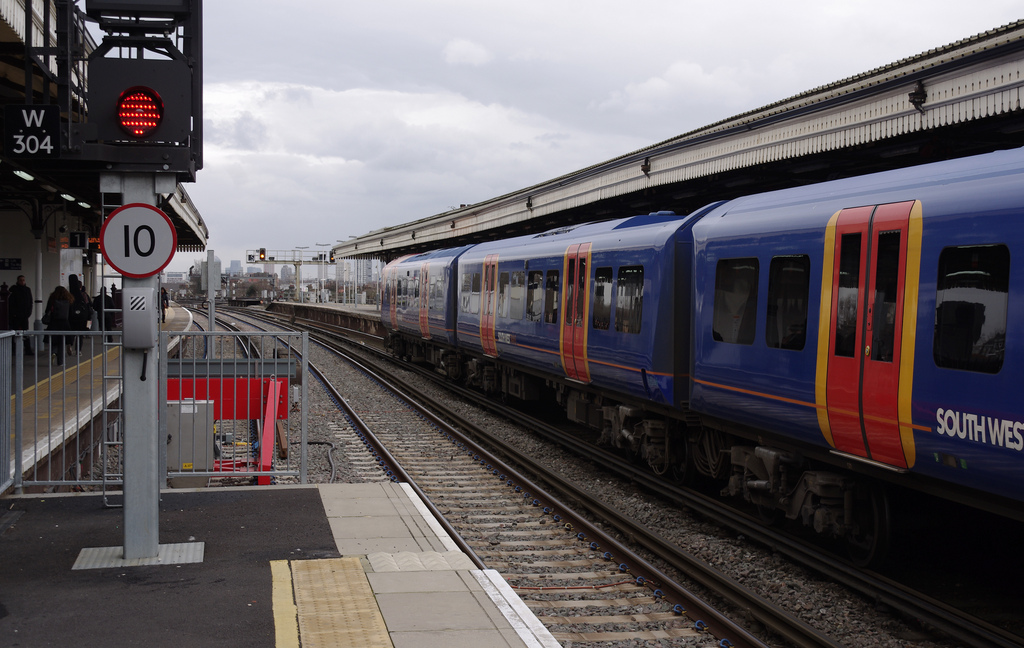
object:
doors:
[807, 192, 928, 476]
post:
[39, 100, 252, 593]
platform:
[0, 176, 427, 644]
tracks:
[222, 299, 1024, 643]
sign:
[88, 186, 184, 282]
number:
[90, 197, 183, 281]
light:
[71, 31, 195, 167]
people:
[0, 266, 183, 367]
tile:
[255, 554, 394, 646]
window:
[929, 240, 1013, 377]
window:
[761, 247, 814, 353]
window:
[710, 247, 761, 347]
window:
[583, 257, 652, 341]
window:
[590, 258, 645, 339]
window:
[449, 252, 486, 319]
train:
[365, 129, 1024, 627]